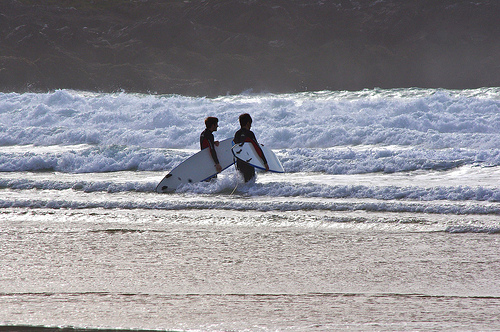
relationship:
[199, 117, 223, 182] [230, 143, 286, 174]
man carrying board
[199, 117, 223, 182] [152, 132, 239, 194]
man carrying surfboard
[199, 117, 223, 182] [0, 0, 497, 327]
man in ocean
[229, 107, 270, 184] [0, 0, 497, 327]
man in ocean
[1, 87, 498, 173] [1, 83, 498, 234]
waves in ocean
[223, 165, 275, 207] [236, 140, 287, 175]
cord dangling from surfboard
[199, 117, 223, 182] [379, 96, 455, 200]
man in ocean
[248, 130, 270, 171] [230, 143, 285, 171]
arm over board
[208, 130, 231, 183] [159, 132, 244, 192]
hands on board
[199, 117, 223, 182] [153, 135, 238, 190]
man carrying surfboard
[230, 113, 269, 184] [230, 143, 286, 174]
man carrying board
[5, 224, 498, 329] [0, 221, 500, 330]
water lapping beach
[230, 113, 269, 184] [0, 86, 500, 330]
man in ocean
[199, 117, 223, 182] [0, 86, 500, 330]
man in ocean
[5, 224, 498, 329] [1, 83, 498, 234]
water of ocean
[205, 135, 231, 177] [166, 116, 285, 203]
arms wrapped around boards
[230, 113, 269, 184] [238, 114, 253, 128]
man has head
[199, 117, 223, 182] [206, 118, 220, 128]
man has head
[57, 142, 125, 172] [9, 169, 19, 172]
wave has ripple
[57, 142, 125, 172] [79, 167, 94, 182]
wave has ripple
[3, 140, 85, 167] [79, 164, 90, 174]
wave has ripple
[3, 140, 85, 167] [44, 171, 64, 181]
wave has ripple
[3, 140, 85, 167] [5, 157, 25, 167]
wave has ripple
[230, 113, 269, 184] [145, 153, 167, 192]
man holds surfboard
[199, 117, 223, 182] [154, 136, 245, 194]
man holds board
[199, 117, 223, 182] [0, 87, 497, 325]
man in water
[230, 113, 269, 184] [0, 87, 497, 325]
man in water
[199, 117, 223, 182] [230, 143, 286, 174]
man holds board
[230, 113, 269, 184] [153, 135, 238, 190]
man holds surfboard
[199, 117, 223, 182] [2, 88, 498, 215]
man in water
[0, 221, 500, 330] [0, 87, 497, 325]
beach on water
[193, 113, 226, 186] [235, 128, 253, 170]
man wears suits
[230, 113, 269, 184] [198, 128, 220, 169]
man wears suits